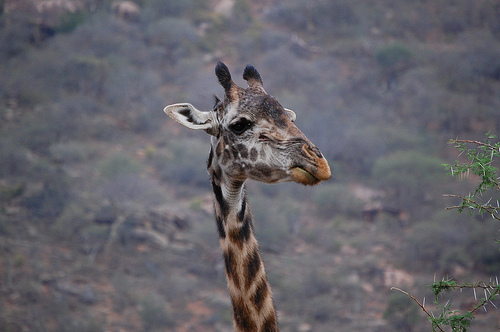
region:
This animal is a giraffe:
[174, 57, 336, 305]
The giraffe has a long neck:
[200, 190, 292, 318]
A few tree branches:
[407, 117, 498, 324]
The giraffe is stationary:
[152, 57, 331, 314]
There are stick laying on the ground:
[66, 180, 195, 255]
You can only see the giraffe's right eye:
[215, 92, 256, 147]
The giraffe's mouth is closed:
[289, 137, 338, 190]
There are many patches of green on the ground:
[35, 57, 158, 262]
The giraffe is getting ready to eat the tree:
[157, 55, 404, 237]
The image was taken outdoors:
[45, 50, 440, 294]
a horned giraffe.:
[168, 26, 331, 328]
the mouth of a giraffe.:
[276, 138, 340, 190]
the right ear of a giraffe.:
[148, 84, 232, 139]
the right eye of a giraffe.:
[203, 86, 265, 148]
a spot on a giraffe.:
[234, 242, 276, 292]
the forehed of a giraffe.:
[209, 37, 301, 127]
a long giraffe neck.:
[206, 178, 296, 330]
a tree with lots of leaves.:
[420, 88, 492, 231]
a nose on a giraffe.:
[307, 131, 341, 184]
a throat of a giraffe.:
[220, 164, 284, 193]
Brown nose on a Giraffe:
[292, 147, 339, 193]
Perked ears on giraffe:
[166, 93, 221, 135]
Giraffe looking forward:
[168, 67, 360, 206]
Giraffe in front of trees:
[176, 70, 358, 229]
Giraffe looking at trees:
[178, 65, 351, 187]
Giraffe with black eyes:
[221, 110, 261, 142]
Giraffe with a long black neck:
[186, 161, 281, 319]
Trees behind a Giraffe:
[121, 35, 208, 262]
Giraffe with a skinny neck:
[200, 183, 301, 284]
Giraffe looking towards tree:
[162, 49, 356, 259]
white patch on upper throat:
[213, 176, 249, 232]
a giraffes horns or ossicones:
[212, 53, 269, 100]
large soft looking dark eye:
[218, 104, 266, 142]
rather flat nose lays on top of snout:
[296, 128, 329, 170]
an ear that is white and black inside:
[142, 79, 234, 131]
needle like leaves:
[388, 108, 498, 330]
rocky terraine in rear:
[1, 1, 214, 331]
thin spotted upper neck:
[201, 151, 293, 329]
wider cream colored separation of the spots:
[214, 168, 285, 330]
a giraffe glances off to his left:
[156, 27, 369, 194]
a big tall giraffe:
[152, 61, 333, 326]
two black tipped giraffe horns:
[200, 64, 272, 97]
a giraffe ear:
[150, 95, 222, 136]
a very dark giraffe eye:
[228, 107, 253, 138]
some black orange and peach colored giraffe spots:
[191, 195, 308, 328]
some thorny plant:
[447, 123, 498, 318]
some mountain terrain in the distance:
[42, 58, 164, 246]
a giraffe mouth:
[285, 166, 339, 188]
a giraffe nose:
[273, 141, 328, 156]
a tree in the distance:
[364, 38, 427, 77]